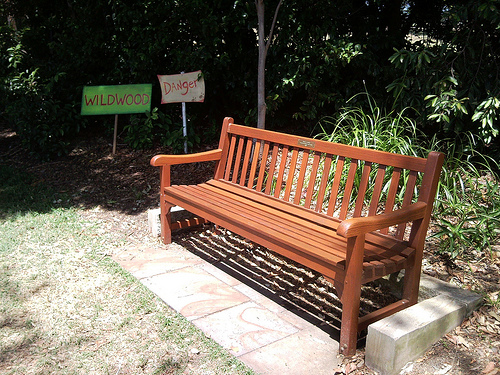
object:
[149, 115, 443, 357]
bench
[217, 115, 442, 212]
back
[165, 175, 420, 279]
bottom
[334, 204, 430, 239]
arm rest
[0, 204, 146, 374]
grass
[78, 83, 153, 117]
sign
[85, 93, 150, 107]
lettering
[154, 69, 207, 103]
sign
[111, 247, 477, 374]
concrete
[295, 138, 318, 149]
plaque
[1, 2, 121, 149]
tree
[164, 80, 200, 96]
danger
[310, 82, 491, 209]
plant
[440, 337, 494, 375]
shadow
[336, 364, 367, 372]
leaf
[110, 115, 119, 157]
pole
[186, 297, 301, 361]
block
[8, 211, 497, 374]
ground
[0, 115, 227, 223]
shadow